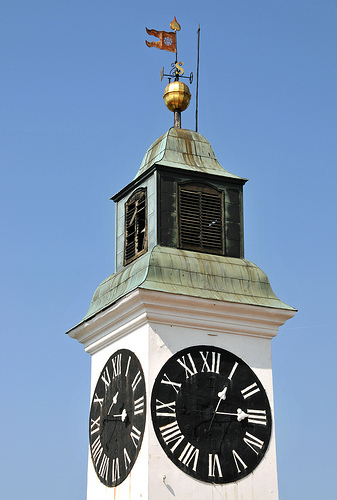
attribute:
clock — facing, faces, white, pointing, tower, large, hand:
[132, 331, 289, 494]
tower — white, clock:
[71, 15, 271, 490]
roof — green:
[57, 254, 291, 345]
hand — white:
[209, 378, 253, 418]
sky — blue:
[25, 75, 112, 218]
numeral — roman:
[200, 345, 217, 367]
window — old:
[165, 167, 257, 265]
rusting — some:
[98, 243, 161, 282]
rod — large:
[167, 8, 221, 153]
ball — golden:
[162, 79, 201, 107]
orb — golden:
[167, 66, 207, 110]